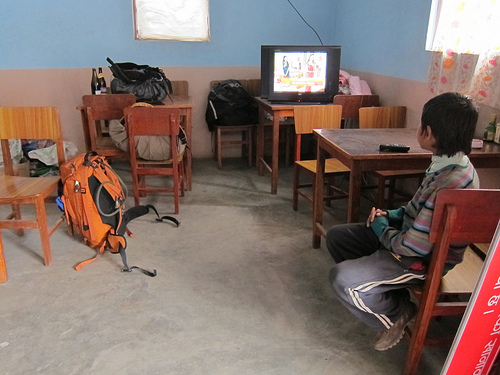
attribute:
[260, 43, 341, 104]
tv — on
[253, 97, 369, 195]
table — wood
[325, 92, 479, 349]
boy — sitting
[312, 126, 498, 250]
table — wood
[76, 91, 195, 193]
table — wood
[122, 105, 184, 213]
chair — wood, brown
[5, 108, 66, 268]
chair — wood, brown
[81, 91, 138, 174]
chair — wood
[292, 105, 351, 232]
chair — wood, brown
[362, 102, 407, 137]
chair — wood, brown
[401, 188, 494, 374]
chair — wood, brown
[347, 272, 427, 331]
stipes — white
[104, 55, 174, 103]
backpack — black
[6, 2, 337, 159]
wall — blue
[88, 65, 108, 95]
beer bottles — opened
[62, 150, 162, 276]
backpack — orange, large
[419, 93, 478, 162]
hair — black